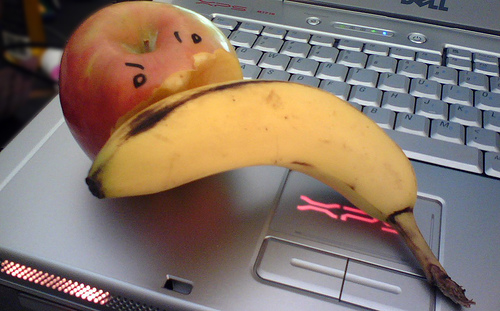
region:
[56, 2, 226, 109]
Apple with eyes drawn on it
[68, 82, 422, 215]
A yellow banana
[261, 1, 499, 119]
Grey keyboard keys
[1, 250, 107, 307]
Lights on a laptop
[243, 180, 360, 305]
Grey mousepad of a laptop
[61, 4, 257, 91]
A red apple on a laptop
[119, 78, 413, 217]
A banana on a laptop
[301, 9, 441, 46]
Power buttons on a laptop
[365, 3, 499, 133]
A DELL laptop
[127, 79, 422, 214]
A bruised banana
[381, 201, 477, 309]
the stem of a banana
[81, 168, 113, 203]
the brown end of a banana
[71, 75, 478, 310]
a yellow banana on the computer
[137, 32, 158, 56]
the stem of an apple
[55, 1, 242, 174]
a red apple on the computer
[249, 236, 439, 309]
the mouse buttons of a laptop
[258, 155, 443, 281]
a laptop touch pad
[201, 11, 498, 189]
a gray computer keyboard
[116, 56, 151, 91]
black marks on the banana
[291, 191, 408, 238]
pink letters on the touch pad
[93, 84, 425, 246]
banana over laptop trackpad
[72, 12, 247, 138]
apple on laptop next to banana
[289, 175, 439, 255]
trackpad says XPS and is lighted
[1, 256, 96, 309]
light on the front of the laptop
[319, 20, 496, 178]
keys are silver with black letters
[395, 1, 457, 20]
dell logo on laptop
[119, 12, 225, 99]
apple has eyes and eyebrows written on it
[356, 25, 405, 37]
blue and green lights on the laptop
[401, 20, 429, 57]
silver power button behind keyboard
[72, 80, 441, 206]
banana has brown spots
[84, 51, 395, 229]
A banana is visible.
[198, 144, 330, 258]
A banana is visible.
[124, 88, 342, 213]
A banana is visible.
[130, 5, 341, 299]
A banana is visible.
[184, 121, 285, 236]
A banana is visible.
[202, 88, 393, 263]
A banana is visible.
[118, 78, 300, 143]
a brown streak on the banana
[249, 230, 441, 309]
gray laptop mouse buttons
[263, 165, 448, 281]
a gray laptop touch pad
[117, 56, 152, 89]
black marks on the apple